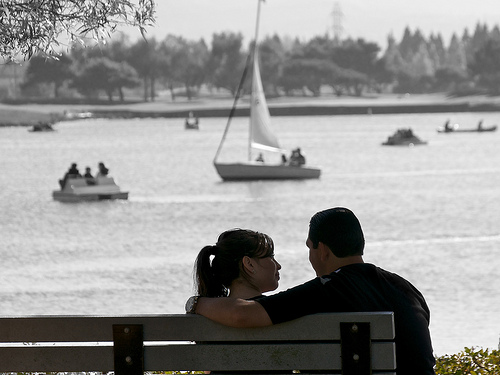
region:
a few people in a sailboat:
[204, 0, 326, 186]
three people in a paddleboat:
[43, 145, 140, 210]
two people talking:
[168, 196, 445, 368]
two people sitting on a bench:
[5, 202, 452, 370]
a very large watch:
[176, 287, 209, 317]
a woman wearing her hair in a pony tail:
[171, 200, 296, 321]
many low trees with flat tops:
[3, 24, 386, 120]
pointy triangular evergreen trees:
[357, 15, 496, 113]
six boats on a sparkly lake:
[22, 0, 492, 237]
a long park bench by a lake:
[0, 297, 424, 372]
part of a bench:
[278, 341, 325, 372]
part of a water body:
[395, 190, 442, 255]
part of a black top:
[393, 312, 415, 347]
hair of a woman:
[188, 245, 220, 285]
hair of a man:
[323, 217, 347, 244]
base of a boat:
[220, 174, 253, 183]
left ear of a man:
[315, 240, 328, 261]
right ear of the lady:
[241, 257, 258, 283]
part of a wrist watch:
[182, 295, 199, 310]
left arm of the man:
[198, 297, 233, 324]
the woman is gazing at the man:
[168, 222, 283, 327]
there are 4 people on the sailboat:
[236, 147, 313, 189]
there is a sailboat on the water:
[213, 67, 308, 192]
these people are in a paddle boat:
[46, 152, 126, 207]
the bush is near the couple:
[433, 342, 495, 372]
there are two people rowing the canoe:
[428, 117, 498, 142]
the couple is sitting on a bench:
[103, 207, 435, 372]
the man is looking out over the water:
[288, 190, 368, 282]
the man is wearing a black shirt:
[276, 265, 438, 372]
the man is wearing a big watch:
[158, 287, 208, 319]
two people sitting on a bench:
[184, 200, 425, 340]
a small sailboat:
[191, 45, 346, 192]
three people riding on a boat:
[56, 125, 148, 198]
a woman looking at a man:
[185, 203, 455, 350]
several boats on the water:
[11, 64, 497, 174]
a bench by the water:
[27, 213, 488, 368]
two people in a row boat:
[415, 98, 497, 142]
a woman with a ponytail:
[195, 218, 302, 371]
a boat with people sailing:
[195, 23, 357, 183]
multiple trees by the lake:
[26, 37, 470, 162]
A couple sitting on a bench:
[175, 200, 450, 370]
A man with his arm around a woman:
[170, 200, 435, 355]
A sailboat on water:
[160, 0, 370, 195]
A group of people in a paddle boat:
[40, 140, 140, 220]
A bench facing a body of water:
[0, 195, 470, 365]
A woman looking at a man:
[160, 190, 450, 365]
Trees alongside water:
[5, 0, 200, 145]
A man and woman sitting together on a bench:
[115, 195, 450, 370]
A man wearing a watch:
[165, 190, 410, 330]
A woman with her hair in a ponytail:
[175, 211, 290, 313]